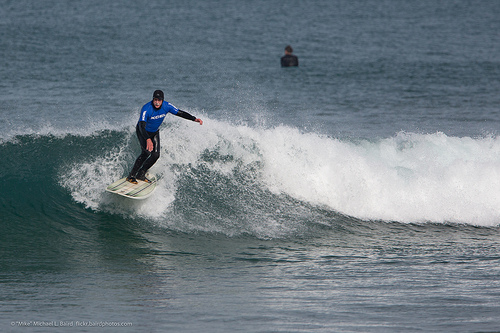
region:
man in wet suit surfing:
[121, 81, 203, 183]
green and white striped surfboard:
[102, 160, 169, 200]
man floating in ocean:
[278, 43, 302, 72]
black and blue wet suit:
[130, 85, 203, 185]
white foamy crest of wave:
[73, 108, 498, 273]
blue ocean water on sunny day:
[13, 0, 498, 319]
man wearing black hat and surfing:
[109, 79, 211, 207]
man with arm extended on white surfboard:
[108, 83, 210, 215]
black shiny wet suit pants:
[118, 125, 172, 188]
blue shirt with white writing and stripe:
[136, 96, 188, 131]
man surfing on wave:
[103, 71, 185, 203]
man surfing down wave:
[87, 73, 217, 228]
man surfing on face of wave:
[95, 85, 202, 205]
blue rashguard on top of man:
[125, 105, 182, 137]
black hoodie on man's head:
[146, 85, 166, 105]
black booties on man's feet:
[121, 178, 153, 188]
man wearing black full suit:
[118, 91, 192, 181]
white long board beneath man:
[112, 172, 162, 204]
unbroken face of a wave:
[0, 125, 86, 262]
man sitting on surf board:
[271, 40, 313, 77]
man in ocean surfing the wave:
[101, 90, 203, 200]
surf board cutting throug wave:
[103, 173, 163, 199]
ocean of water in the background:
[2, 1, 498, 127]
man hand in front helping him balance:
[144, 140, 156, 152]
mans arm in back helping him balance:
[166, 101, 206, 127]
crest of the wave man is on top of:
[133, 113, 498, 167]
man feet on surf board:
[126, 175, 151, 185]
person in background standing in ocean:
[278, 45, 299, 67]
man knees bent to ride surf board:
[141, 151, 161, 156]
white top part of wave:
[258, 129, 499, 226]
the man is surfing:
[71, 78, 217, 260]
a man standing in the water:
[257, 33, 342, 126]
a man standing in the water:
[261, 28, 314, 89]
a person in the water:
[276, 44, 301, 70]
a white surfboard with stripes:
[104, 161, 168, 199]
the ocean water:
[1, 0, 496, 329]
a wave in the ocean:
[1, 114, 496, 231]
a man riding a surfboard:
[126, 86, 202, 186]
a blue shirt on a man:
[138, 101, 178, 135]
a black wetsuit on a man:
[127, 101, 194, 178]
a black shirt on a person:
[278, 54, 302, 70]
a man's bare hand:
[145, 136, 155, 155]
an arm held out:
[168, 101, 205, 124]